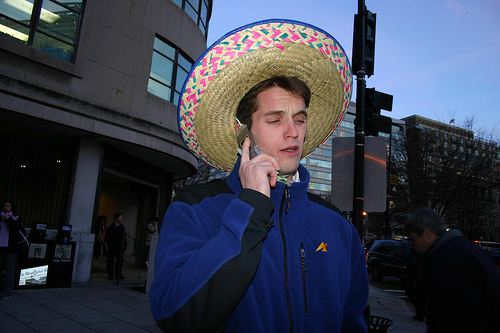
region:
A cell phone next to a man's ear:
[230, 116, 255, 158]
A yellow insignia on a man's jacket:
[312, 239, 334, 255]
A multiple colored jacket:
[157, 172, 375, 327]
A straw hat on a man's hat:
[172, 15, 353, 175]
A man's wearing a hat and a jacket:
[140, 11, 404, 331]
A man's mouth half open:
[275, 142, 302, 157]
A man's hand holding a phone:
[230, 133, 290, 198]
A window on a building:
[164, 50, 186, 84]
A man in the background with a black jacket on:
[100, 210, 137, 290]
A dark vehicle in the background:
[363, 238, 402, 263]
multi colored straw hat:
[173, 19, 353, 174]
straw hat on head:
[173, 18, 352, 168]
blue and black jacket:
[148, 159, 373, 331]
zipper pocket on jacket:
[299, 244, 308, 317]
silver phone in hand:
[236, 124, 262, 162]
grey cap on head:
[395, 205, 446, 238]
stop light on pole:
[353, 4, 392, 251]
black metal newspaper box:
[48, 224, 77, 288]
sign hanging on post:
[330, 137, 386, 212]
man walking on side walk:
[104, 212, 127, 284]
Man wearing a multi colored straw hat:
[168, 15, 363, 182]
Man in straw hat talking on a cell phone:
[165, 16, 371, 214]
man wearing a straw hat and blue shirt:
[145, 15, 376, 330]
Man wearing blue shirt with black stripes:
[143, 14, 392, 331]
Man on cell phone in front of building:
[115, 1, 372, 331]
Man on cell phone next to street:
[144, 15, 498, 332]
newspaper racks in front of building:
[1, 120, 116, 328]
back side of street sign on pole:
[321, 39, 451, 331]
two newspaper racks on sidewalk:
[1, 215, 96, 306]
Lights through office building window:
[0, 0, 141, 127]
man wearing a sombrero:
[153, 14, 391, 327]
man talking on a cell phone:
[182, 34, 377, 303]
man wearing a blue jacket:
[158, 10, 386, 320]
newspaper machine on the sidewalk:
[15, 220, 52, 285]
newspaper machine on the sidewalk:
[53, 220, 78, 292]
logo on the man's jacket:
[315, 225, 330, 263]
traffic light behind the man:
[345, 0, 400, 226]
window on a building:
[147, 26, 183, 106]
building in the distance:
[407, 111, 487, 181]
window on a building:
[32, 5, 84, 57]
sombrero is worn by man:
[175, 17, 352, 179]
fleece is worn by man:
[146, 145, 376, 331]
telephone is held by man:
[231, 122, 258, 159]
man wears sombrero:
[145, 75, 371, 332]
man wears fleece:
[152, 75, 371, 332]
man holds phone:
[150, 77, 371, 331]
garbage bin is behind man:
[360, 312, 392, 332]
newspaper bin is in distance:
[44, 219, 76, 290]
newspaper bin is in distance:
[17, 221, 54, 288]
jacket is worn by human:
[407, 227, 499, 331]